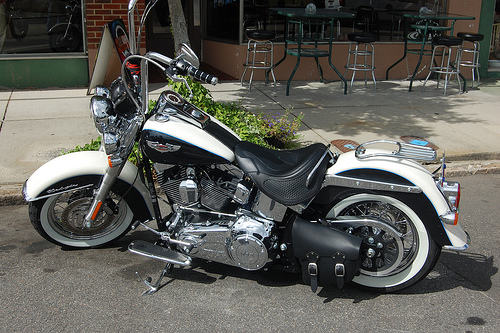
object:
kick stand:
[135, 263, 171, 296]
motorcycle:
[21, 0, 472, 295]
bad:
[292, 219, 363, 293]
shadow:
[162, 252, 498, 304]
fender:
[326, 149, 465, 247]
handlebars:
[127, 0, 219, 111]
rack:
[355, 139, 438, 161]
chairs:
[241, 29, 277, 91]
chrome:
[127, 163, 291, 271]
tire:
[29, 175, 142, 250]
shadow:
[215, 80, 486, 140]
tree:
[168, 0, 192, 54]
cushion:
[235, 140, 334, 205]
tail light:
[439, 180, 461, 225]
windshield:
[127, 2, 163, 111]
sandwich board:
[86, 17, 149, 95]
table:
[265, 5, 355, 96]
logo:
[146, 140, 182, 154]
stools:
[341, 32, 487, 96]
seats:
[433, 36, 464, 46]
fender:
[21, 150, 156, 220]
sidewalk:
[1, 76, 500, 199]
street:
[1, 174, 500, 332]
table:
[386, 7, 475, 92]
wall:
[202, 0, 481, 81]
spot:
[24, 238, 55, 252]